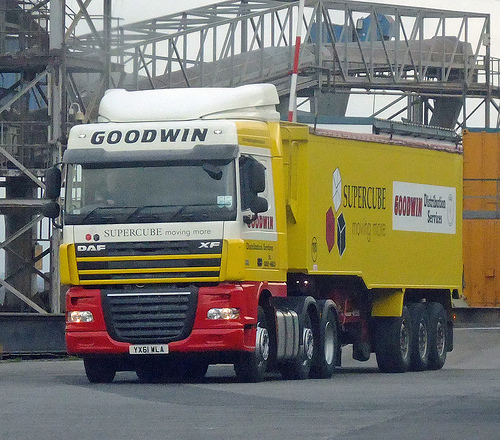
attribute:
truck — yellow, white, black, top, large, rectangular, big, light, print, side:
[50, 53, 486, 323]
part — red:
[202, 295, 254, 352]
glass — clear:
[94, 151, 224, 218]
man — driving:
[99, 152, 149, 226]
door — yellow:
[201, 136, 311, 331]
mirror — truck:
[220, 157, 288, 225]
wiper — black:
[71, 198, 225, 251]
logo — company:
[298, 185, 370, 272]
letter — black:
[61, 107, 226, 182]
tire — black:
[361, 293, 448, 379]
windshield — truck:
[94, 163, 226, 237]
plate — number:
[107, 327, 182, 396]